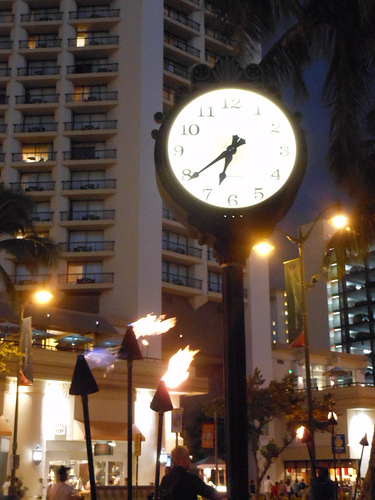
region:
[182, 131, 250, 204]
Black hands on clock.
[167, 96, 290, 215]
Black numbers on clock.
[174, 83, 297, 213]
Face of clock is illuminated.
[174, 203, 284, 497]
Clock is connected to black pole.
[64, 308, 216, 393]
Flames coming out of torches.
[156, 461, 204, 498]
Person wearing black shirt.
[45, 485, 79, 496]
Person wearing white shirt.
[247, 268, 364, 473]
Large buildings in the background.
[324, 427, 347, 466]
Blue sign near building.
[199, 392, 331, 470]
Large tree near building.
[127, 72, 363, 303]
Large clock on a pole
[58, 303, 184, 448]
Torches on tall poles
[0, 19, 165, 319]
A very tall building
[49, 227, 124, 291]
Balconies on a building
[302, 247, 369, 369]
Parking garage with several levels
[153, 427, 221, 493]
A person outside at night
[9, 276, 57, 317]
Street light at night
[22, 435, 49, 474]
A light on a building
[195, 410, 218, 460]
An orange flag on a pole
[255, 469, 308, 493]
People waiting in line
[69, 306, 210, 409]
Flames of fire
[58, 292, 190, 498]
Three tourches burning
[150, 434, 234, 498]
A guy dressed in black walking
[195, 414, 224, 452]
A hanging orange banner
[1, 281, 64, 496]
A street light that is on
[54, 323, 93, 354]
A green umbrella with a light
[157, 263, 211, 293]
a gated balcony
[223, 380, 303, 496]
A tree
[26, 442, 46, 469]
A light that is turned on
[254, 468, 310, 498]
A group of people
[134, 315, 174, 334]
a flame caught in a sideways gust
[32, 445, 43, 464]
a glowing street lamp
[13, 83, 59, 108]
a single apartment balcony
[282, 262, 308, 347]
a city banner on a pole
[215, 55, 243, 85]
a large seashell shaped decoration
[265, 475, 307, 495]
a crowd of people at a shopping center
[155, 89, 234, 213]
the left half of a clock lit up at night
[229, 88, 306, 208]
the right half of a clock lit up at night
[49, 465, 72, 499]
a woman with a hat on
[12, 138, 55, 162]
a balcony with the inside lights on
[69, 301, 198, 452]
torches lit at night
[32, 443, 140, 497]
entry to a hotel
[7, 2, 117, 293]
hotel rooms with balconies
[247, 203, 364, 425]
double globed street light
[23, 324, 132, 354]
green umbrella of tables on upper terrace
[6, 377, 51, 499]
wall mounted light on outside pillar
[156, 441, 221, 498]
man passing by wears black shirt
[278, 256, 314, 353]
banner attached high on a pole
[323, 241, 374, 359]
lighted windows on a neighboring building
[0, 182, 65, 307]
branches of a palm tree